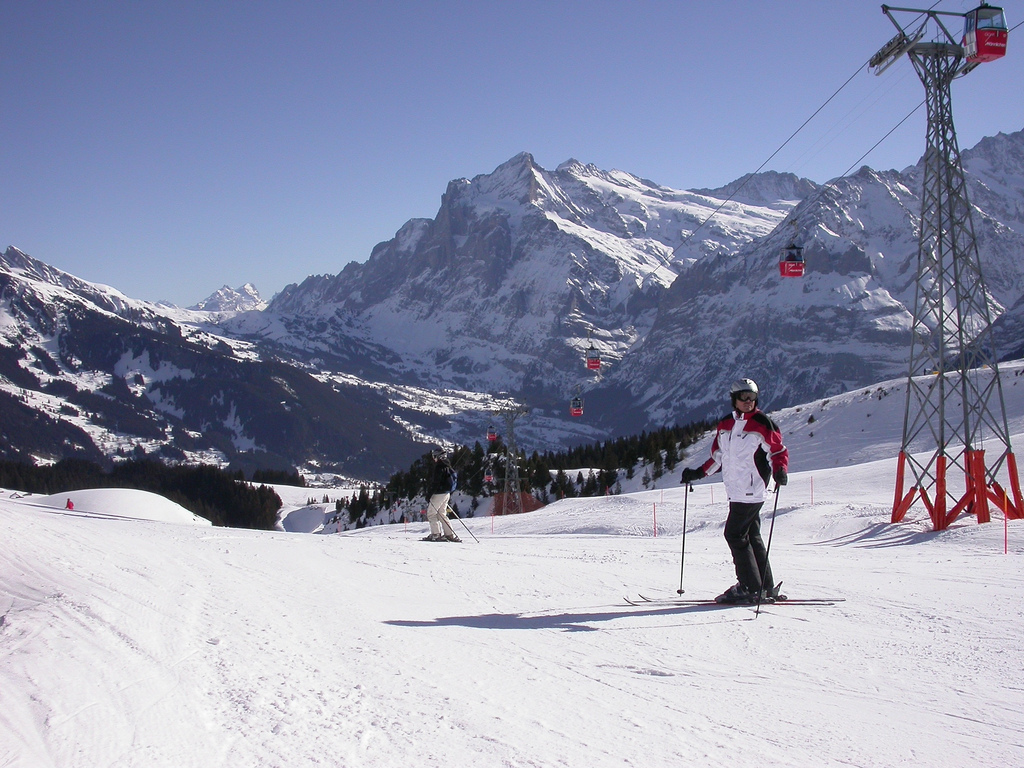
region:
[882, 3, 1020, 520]
Ski lift cable support structure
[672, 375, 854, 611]
Stationary helmeted skier looking back uphill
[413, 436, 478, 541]
Skier in light colored trousers moving downhill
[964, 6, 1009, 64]
Ski lift cab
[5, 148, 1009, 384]
Mountain range in the distance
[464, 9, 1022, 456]
Ski lift cable lines running up the mountain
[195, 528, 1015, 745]
Ski run packed surface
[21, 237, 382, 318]
Mountain gap in the distance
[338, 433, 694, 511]
Evergreen trees along ski run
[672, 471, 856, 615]
Skis and ski poles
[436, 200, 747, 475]
snow on a mountain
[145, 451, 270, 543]
green leaves on the tree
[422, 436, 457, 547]
person wearing pants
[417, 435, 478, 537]
a person wearing jacket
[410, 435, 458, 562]
a person on skis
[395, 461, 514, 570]
a person holding ski pole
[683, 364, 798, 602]
a person wearing a jacket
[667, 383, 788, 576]
a person wearing pants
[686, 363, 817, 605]
a person is on skis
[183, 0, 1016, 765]
scene at a snow ski area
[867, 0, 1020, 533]
tower for cable to gondola ski lift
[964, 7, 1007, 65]
red gondola on a ski lift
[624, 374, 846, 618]
skier with black pants and a white red and black parka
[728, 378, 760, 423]
white and black helmet on a skier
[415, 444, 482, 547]
skier with white pants and black parka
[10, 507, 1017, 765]
ski tracks in the packed snow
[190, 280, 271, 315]
mountain peak in the background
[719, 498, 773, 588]
the pants are black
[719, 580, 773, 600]
the boots are black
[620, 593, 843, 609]
the skis are white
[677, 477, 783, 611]
the poles are gray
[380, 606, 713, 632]
shadow on the ground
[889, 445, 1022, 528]
the paint is red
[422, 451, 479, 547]
a guy is skiing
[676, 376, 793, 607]
the person is on the snow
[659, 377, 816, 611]
the person is skiing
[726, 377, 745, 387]
the person wears a helmet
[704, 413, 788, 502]
the person wears a jacket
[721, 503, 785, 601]
the person wears long pants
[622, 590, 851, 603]
the person is on skiis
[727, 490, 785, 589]
the person wears black pants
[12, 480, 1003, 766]
the ground is covered in snow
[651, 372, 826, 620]
the person is outdoors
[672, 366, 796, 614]
Skier with white jacket and red trim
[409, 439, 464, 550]
Skier with dark jacket and white pants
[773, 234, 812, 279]
Ski lift compartment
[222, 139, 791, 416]
Snow covered mountain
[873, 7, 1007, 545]
Ski lift tower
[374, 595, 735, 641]
Man's shadow in the snow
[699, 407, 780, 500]
man wearing a red and white jacket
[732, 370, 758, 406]
man wearing a silver helmet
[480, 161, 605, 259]
snow on the side of the mountain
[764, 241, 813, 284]
ski lift above the ground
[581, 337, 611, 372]
ski lift above the ground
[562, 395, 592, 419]
ski lift above the ground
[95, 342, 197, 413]
snow on the side of mountain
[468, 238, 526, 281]
white snow on the mountain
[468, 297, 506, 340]
white snow on the mountain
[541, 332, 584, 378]
white snow on the mountain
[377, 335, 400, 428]
white snow on the mountain